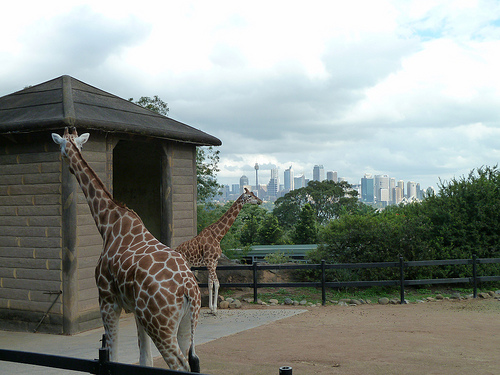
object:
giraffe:
[51, 126, 200, 371]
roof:
[2, 76, 222, 146]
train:
[228, 243, 318, 266]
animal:
[175, 188, 263, 315]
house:
[1, 74, 225, 334]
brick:
[28, 190, 62, 203]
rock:
[267, 298, 278, 304]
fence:
[186, 257, 499, 305]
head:
[52, 126, 91, 165]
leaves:
[373, 216, 384, 226]